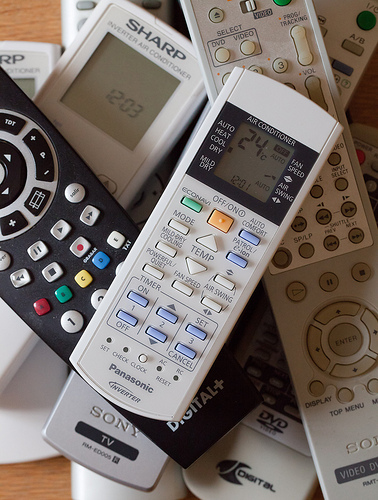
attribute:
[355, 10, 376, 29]
button — on/off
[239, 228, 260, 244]
button — blue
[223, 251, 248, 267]
button — blue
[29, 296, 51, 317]
button — red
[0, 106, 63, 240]
buttons — black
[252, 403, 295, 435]
logo — dvd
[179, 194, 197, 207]
button — green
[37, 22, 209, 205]
remote — white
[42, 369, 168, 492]
remote control — Sony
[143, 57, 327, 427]
remote — Panasonic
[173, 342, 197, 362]
button — blue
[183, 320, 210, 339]
button — blue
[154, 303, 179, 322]
button — blue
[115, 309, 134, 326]
button — blue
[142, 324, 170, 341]
button — blue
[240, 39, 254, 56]
button — video, DVD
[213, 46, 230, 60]
button — video, DVD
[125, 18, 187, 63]
logo — sharp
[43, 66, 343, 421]
remote — different, white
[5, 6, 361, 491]
table — wooden